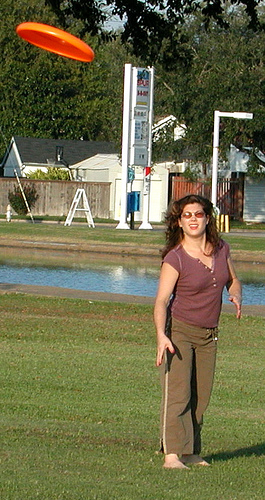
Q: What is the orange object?
A: Frisbee.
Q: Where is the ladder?
A: In front of the fence.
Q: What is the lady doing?
A: Getting ready to catch a frisbee.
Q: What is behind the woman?
A: A large pond.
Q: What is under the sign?
A: Two pay phones.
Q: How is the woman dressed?
A: Pants and a t-shirt.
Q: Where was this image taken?
A: In a park.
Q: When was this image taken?
A: In the afternoon.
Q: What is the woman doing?
A: Playing frisbee.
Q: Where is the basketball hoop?
A: Behind the wooden fence in the background.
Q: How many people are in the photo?
A: One woman.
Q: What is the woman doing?
A: Playing frisbee.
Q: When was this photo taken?
A: During the day.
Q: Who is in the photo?
A: A woman.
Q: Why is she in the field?
A: Playing frisbee.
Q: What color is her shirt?
A: Maroon.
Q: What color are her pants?
A: Brown.